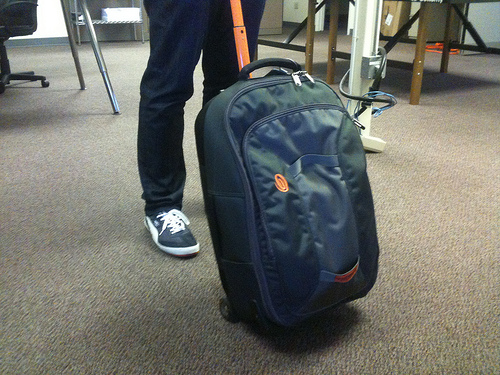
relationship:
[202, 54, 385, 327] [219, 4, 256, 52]
backpack being carried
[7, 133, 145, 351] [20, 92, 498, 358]
carpet on ground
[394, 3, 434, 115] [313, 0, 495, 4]
legs on a table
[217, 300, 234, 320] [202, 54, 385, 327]
wheels on backpack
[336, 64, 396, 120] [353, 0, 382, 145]
wiring on pole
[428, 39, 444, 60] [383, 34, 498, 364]
cord on floor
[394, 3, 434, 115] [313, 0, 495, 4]
legs of a table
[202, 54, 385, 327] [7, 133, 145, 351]
luggage on carpet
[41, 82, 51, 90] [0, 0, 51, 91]
wheel on chair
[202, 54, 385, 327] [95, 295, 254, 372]
luggage has a shadow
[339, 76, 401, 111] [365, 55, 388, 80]
wires around junction box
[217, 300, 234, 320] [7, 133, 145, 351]
wheels on carpet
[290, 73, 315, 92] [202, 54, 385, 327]
zippers on bag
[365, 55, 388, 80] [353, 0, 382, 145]
box on post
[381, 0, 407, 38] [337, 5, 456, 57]
cardboard box in background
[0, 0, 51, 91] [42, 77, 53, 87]
office chair on wheels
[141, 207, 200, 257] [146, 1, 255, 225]
foot attached to legs